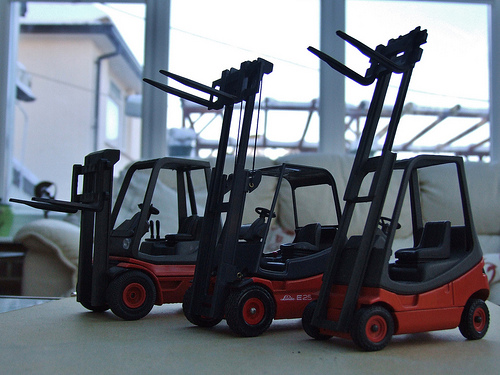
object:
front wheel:
[110, 268, 159, 322]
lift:
[9, 148, 209, 321]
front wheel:
[223, 281, 278, 339]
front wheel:
[353, 302, 396, 352]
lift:
[305, 25, 490, 353]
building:
[9, 8, 144, 216]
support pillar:
[139, 1, 174, 158]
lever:
[142, 55, 278, 177]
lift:
[142, 56, 345, 338]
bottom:
[269, 273, 323, 320]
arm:
[142, 56, 276, 112]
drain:
[0, 294, 65, 312]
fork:
[146, 56, 275, 323]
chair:
[278, 222, 322, 260]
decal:
[277, 292, 315, 303]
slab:
[47, 218, 75, 227]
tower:
[168, 126, 198, 160]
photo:
[0, 0, 500, 373]